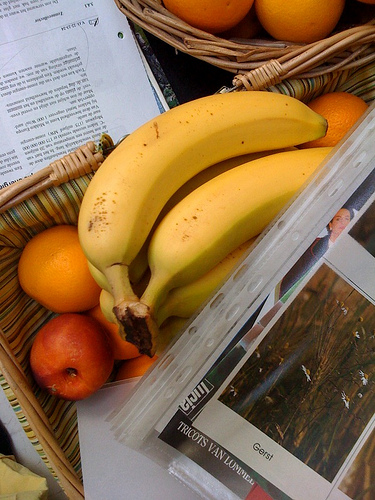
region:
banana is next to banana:
[77, 89, 326, 301]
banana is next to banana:
[150, 236, 276, 334]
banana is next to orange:
[77, 90, 329, 302]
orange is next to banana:
[298, 91, 368, 146]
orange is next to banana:
[16, 220, 98, 311]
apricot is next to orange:
[28, 312, 113, 399]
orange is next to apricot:
[90, 301, 141, 361]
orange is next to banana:
[92, 303, 149, 360]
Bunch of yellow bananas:
[73, 88, 336, 358]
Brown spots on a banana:
[83, 186, 119, 238]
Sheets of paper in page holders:
[108, 96, 373, 498]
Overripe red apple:
[26, 311, 111, 401]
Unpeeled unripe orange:
[12, 223, 100, 315]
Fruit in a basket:
[12, 86, 373, 405]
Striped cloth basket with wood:
[0, 24, 374, 498]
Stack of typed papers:
[1, 0, 169, 197]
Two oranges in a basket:
[113, 0, 374, 79]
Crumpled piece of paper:
[1, 449, 52, 498]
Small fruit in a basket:
[18, 223, 96, 310]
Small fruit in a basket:
[27, 301, 114, 409]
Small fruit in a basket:
[98, 316, 147, 363]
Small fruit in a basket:
[56, 106, 280, 322]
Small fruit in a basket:
[305, 102, 373, 151]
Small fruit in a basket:
[254, 0, 332, 48]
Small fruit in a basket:
[164, 1, 261, 37]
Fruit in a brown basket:
[6, 172, 281, 498]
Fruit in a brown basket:
[115, 4, 373, 89]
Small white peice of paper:
[66, 418, 160, 497]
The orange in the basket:
[20, 228, 86, 304]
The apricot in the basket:
[28, 308, 109, 408]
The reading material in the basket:
[120, 152, 372, 498]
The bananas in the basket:
[63, 83, 315, 329]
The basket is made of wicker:
[1, 149, 117, 488]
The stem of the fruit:
[60, 361, 83, 382]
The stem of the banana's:
[103, 269, 162, 358]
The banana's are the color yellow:
[104, 117, 317, 264]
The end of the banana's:
[308, 107, 331, 143]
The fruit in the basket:
[9, 64, 369, 434]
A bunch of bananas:
[67, 89, 353, 358]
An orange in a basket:
[34, 317, 115, 408]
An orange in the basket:
[2, 225, 98, 316]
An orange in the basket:
[90, 302, 147, 358]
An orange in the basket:
[305, 80, 369, 149]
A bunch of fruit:
[14, 94, 362, 404]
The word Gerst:
[255, 439, 273, 464]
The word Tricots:
[178, 419, 207, 449]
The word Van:
[209, 438, 226, 462]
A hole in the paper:
[111, 26, 127, 40]